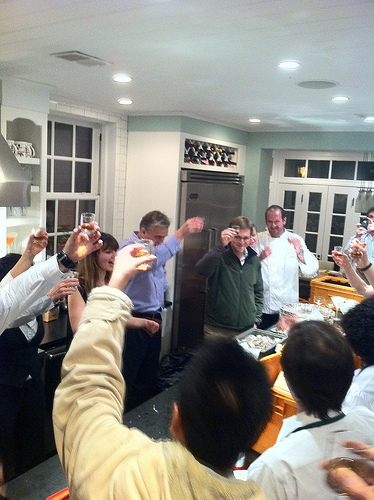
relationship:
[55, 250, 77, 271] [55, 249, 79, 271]
watch on wrist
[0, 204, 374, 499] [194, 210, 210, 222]
people holding glass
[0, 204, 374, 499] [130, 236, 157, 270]
people raises glass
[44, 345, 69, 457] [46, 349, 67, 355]
dish washer has handle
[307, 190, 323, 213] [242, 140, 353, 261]
pane has door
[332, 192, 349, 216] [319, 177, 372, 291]
pane on door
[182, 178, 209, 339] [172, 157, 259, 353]
pane on door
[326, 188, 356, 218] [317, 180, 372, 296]
pane on door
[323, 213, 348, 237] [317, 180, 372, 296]
pane on door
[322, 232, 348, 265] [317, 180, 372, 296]
pane on door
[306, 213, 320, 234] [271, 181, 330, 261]
pane on door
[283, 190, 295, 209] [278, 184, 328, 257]
pane on door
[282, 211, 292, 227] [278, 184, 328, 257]
pane on door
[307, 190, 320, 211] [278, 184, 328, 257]
pane on door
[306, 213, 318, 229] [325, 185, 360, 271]
pane on door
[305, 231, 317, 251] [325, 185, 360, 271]
pane on door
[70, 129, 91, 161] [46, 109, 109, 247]
pane on door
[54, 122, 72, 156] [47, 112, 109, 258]
pane on door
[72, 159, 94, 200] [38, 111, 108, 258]
pane on door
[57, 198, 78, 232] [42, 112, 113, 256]
pane on door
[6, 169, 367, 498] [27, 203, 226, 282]
people holding glasses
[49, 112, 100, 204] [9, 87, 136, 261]
window on background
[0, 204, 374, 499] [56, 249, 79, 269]
people wears watch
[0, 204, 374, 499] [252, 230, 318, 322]
people wears outfit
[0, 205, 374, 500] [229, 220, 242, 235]
man wears glass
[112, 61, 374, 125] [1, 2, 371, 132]
lights on ceiling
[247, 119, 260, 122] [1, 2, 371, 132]
lights on ceiling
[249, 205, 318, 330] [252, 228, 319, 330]
man in outfit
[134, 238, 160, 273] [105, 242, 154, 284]
glass in a hand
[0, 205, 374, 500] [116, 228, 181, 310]
man wearing shirt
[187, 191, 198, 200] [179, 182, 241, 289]
logo on door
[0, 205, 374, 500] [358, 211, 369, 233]
man using cell phone